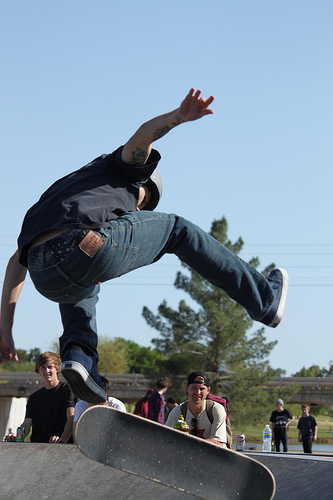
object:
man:
[0, 86, 287, 404]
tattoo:
[128, 147, 148, 167]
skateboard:
[73, 403, 276, 498]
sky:
[0, 1, 331, 371]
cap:
[148, 170, 169, 201]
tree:
[149, 214, 282, 436]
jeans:
[27, 210, 275, 362]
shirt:
[17, 143, 161, 268]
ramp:
[0, 443, 74, 489]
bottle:
[262, 423, 274, 453]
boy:
[162, 369, 227, 447]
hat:
[186, 370, 210, 391]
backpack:
[204, 392, 234, 450]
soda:
[235, 433, 245, 450]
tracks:
[284, 375, 322, 403]